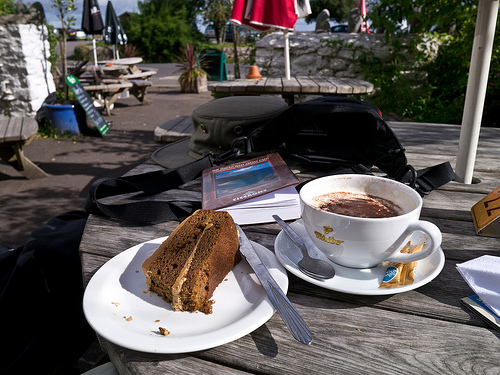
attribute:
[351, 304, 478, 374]
surface — gray, wood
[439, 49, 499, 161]
pole — white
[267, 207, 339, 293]
spoon — metal, gray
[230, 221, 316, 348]
knife — gray, metal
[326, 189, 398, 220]
hot chocolate — chocolate 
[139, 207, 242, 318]
cake — a piece, chocolate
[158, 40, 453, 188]
bag — black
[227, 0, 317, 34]
umbrella — red and closed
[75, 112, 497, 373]
table — wood, wooden, round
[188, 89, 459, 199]
fanny pack — black, for fanny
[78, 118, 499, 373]
round tables — several,round and wood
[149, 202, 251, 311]
cake — chocolate 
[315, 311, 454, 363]
table — grey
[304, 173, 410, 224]
liquid — thick